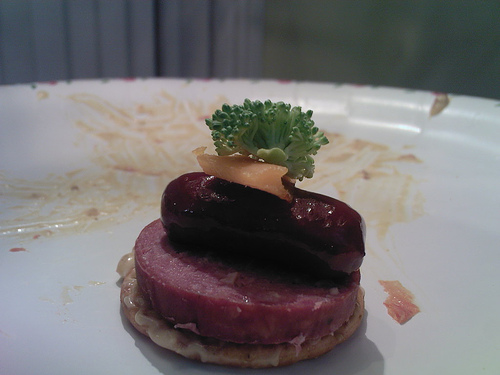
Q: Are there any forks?
A: No, there are no forks.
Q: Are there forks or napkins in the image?
A: No, there are no forks or napkins.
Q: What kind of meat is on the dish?
A: The meat is ham.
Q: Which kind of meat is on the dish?
A: The meat is ham.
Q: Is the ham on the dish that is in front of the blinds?
A: Yes, the ham is on the dish.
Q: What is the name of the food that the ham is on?
A: The food is meat.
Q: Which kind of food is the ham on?
A: The ham is on the meat.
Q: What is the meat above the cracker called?
A: The meat is ham.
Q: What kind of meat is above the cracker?
A: The meat is ham.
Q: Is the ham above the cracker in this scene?
A: Yes, the ham is above the cracker.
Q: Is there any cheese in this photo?
A: Yes, there is cheese.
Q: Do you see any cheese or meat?
A: Yes, there is cheese.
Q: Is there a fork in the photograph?
A: No, there are no forks.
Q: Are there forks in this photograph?
A: No, there are no forks.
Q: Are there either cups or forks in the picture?
A: No, there are no forks or cups.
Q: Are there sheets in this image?
A: No, there are no sheets.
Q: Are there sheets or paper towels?
A: No, there are no sheets or paper towels.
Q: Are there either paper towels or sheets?
A: No, there are no sheets or paper towels.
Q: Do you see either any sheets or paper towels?
A: No, there are no sheets or paper towels.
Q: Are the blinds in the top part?
A: Yes, the blinds are in the top of the image.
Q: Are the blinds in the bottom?
A: No, the blinds are in the top of the image.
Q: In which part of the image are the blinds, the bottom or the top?
A: The blinds are in the top of the image.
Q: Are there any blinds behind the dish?
A: Yes, there are blinds behind the dish.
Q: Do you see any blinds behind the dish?
A: Yes, there are blinds behind the dish.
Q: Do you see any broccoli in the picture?
A: Yes, there is broccoli.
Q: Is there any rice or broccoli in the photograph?
A: Yes, there is broccoli.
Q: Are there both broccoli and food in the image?
A: Yes, there are both broccoli and food.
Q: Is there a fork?
A: No, there are no forks.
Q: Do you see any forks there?
A: No, there are no forks.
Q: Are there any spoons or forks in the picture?
A: No, there are no forks or spoons.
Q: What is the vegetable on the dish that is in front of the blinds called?
A: The vegetable is broccoli.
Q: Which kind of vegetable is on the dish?
A: The vegetable is broccoli.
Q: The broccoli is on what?
A: The broccoli is on the dish.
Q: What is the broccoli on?
A: The broccoli is on the dish.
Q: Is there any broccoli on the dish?
A: Yes, there is broccoli on the dish.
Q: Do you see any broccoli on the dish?
A: Yes, there is broccoli on the dish.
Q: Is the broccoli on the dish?
A: Yes, the broccoli is on the dish.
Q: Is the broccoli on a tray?
A: No, the broccoli is on the dish.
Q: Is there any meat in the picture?
A: Yes, there is meat.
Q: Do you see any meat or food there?
A: Yes, there is meat.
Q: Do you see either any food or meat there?
A: Yes, there is meat.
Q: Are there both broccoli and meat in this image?
A: Yes, there are both meat and broccoli.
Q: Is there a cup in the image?
A: No, there are no cups.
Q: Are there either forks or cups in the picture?
A: No, there are no cups or forks.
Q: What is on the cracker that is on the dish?
A: The meat is on the cracker.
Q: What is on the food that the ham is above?
A: The meat is on the cracker.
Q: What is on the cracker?
A: The meat is on the cracker.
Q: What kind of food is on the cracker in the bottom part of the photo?
A: The food is meat.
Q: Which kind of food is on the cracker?
A: The food is meat.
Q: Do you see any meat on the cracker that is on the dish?
A: Yes, there is meat on the cracker.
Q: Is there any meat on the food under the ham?
A: Yes, there is meat on the cracker.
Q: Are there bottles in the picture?
A: No, there are no bottles.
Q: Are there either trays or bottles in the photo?
A: No, there are no bottles or trays.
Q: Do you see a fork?
A: No, there are no forks.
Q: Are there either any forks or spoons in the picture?
A: No, there are no forks or spoons.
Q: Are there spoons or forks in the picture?
A: No, there are no forks or spoons.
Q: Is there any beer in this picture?
A: No, there is no beer.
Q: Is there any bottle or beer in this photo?
A: No, there are no beer or bottles.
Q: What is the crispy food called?
A: The food is a cracker.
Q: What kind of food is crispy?
A: The food is a cracker.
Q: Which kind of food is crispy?
A: The food is a cracker.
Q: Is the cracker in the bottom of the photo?
A: Yes, the cracker is in the bottom of the image.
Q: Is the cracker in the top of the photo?
A: No, the cracker is in the bottom of the image.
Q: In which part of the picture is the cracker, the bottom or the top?
A: The cracker is in the bottom of the image.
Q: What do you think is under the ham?
A: The cracker is under the ham.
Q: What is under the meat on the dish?
A: The cracker is under the ham.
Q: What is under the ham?
A: The cracker is under the ham.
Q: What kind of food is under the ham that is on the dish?
A: The food is a cracker.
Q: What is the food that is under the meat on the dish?
A: The food is a cracker.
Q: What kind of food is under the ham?
A: The food is a cracker.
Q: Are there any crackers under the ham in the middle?
A: Yes, there is a cracker under the ham.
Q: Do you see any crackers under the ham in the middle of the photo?
A: Yes, there is a cracker under the ham.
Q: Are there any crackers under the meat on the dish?
A: Yes, there is a cracker under the ham.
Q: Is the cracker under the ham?
A: Yes, the cracker is under the ham.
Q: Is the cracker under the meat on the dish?
A: Yes, the cracker is under the ham.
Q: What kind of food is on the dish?
A: The food is a cracker.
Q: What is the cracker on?
A: The cracker is on the dish.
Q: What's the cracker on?
A: The cracker is on the dish.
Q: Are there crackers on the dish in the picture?
A: Yes, there is a cracker on the dish.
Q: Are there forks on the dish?
A: No, there is a cracker on the dish.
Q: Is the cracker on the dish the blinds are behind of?
A: Yes, the cracker is on the dish.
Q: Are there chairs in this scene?
A: No, there are no chairs.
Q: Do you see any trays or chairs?
A: No, there are no chairs or trays.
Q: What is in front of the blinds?
A: The dish is in front of the blinds.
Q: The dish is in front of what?
A: The dish is in front of the blinds.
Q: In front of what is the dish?
A: The dish is in front of the blinds.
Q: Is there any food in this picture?
A: Yes, there is food.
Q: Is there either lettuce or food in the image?
A: Yes, there is food.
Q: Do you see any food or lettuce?
A: Yes, there is food.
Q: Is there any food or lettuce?
A: Yes, there is food.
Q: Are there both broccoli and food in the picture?
A: Yes, there are both food and broccoli.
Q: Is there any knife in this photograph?
A: No, there are no knives.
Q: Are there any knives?
A: No, there are no knives.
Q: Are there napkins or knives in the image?
A: No, there are no knives or napkins.